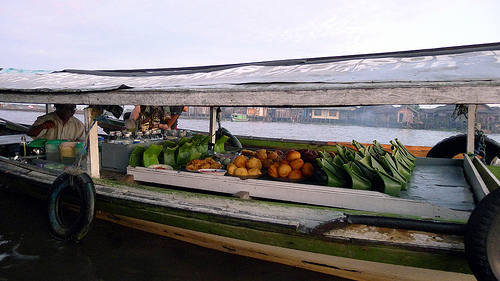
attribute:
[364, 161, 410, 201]
leaf — green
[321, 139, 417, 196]
bags — green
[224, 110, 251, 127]
boat — small, green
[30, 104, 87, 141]
shirt — button up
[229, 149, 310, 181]
fruits — yellow, fresh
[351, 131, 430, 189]
leaf — cover, green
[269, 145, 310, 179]
fruits — orange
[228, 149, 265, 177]
fruits — orange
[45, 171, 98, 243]
ring — rubber, black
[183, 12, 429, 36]
sky — white, hazy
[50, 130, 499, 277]
tires — black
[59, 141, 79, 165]
container — large, plastic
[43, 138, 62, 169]
container — plastic, large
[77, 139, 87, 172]
container — plastic, large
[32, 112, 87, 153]
shirt — white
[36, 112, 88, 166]
shirt — white, button up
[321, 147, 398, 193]
leaf — green, cover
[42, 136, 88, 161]
containers — large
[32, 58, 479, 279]
boat — metal, wood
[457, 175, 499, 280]
tire — round, black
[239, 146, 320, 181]
fruit — fresh, yellow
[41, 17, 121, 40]
sky — cloudy, blue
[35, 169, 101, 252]
tire — black, rubber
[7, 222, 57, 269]
tire — black, rubber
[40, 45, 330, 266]
boat — wood, metal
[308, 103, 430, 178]
leaf — green, cover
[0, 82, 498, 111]
roof — gray, white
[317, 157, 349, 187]
leaf — cover, green